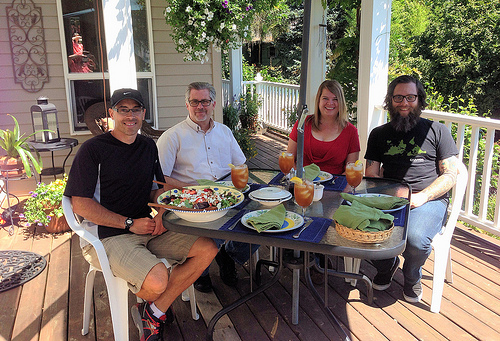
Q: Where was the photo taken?
A: On a porch.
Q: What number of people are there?
A: Four.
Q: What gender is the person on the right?
A: Male.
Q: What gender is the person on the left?
A: Male.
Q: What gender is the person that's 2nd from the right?
A: Female.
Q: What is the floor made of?
A: Wood.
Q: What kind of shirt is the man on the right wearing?
A: A t-shirt.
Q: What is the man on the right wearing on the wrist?
A: A watch.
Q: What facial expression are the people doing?
A: Smiling.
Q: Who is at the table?
A: A man.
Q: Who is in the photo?
A: A young man.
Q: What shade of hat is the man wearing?
A: Black.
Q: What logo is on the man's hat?
A: Nike.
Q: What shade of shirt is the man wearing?
A: White.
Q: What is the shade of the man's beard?
A: Gray.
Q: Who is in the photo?
A: A woman.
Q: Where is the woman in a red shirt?
A: Sitting at the table.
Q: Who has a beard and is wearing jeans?
A: The man on the far right.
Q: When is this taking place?
A: Daytime.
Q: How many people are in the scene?
A: Four.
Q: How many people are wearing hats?
A: One.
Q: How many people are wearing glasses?
A: Three.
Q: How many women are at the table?
A: One.